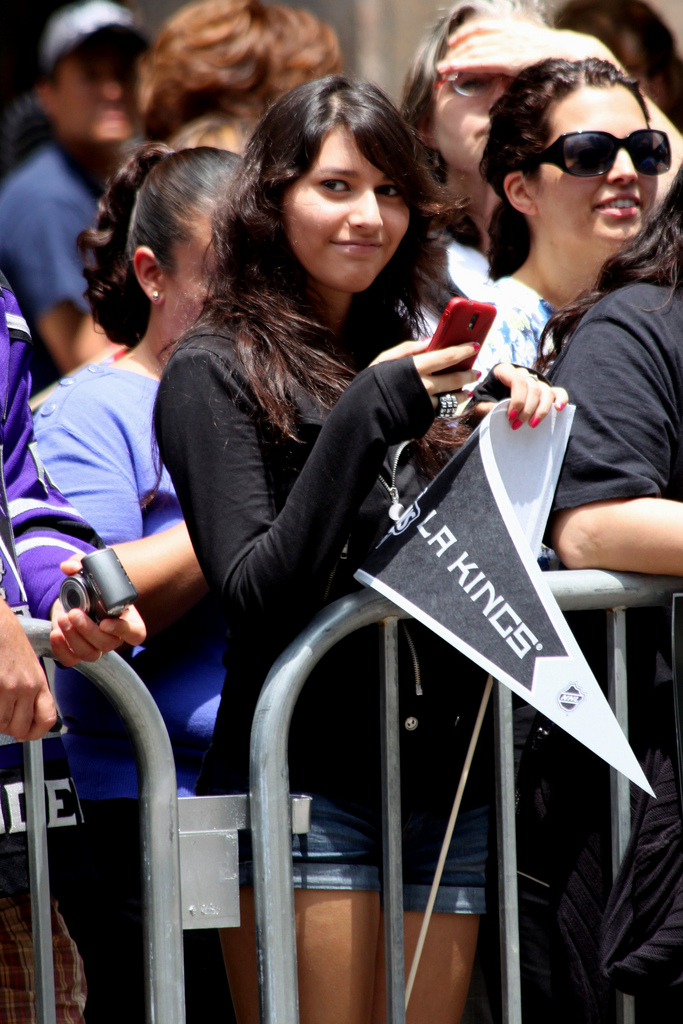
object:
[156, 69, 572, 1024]
woman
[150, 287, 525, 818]
shirt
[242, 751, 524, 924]
shorts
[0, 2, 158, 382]
man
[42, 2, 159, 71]
hat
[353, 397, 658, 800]
flag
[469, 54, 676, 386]
woman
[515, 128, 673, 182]
sunglasses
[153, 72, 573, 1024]
girl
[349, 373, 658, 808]
banner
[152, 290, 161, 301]
earring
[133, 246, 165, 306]
ear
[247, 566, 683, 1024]
barricade